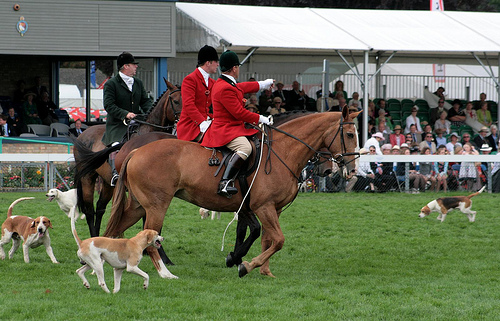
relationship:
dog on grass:
[74, 228, 164, 295] [2, 190, 496, 319]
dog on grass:
[0, 196, 59, 264] [2, 190, 496, 319]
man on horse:
[102, 51, 149, 186] [65, 77, 193, 263]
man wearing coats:
[198, 54, 293, 196] [199, 75, 258, 148]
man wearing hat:
[198, 54, 293, 196] [221, 50, 241, 70]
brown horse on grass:
[98, 103, 363, 277] [337, 196, 455, 291]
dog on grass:
[43, 186, 87, 223] [2, 190, 496, 319]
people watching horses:
[257, 70, 497, 189] [71, 79, 365, 278]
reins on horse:
[262, 111, 361, 183] [103, 106, 360, 276]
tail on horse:
[69, 129, 127, 183] [54, 130, 174, 244]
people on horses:
[97, 40, 277, 209] [71, 79, 365, 278]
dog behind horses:
[43, 186, 87, 223] [71, 79, 365, 278]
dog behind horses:
[74, 228, 164, 295] [71, 79, 365, 278]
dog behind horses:
[0, 193, 57, 266] [71, 79, 365, 278]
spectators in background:
[3, 78, 498, 190] [0, 0, 497, 158]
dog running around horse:
[74, 228, 164, 295] [103, 106, 360, 276]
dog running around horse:
[0, 196, 59, 264] [103, 106, 360, 276]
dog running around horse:
[43, 186, 87, 223] [103, 106, 360, 276]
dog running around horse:
[74, 228, 164, 295] [74, 71, 188, 271]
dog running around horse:
[0, 196, 59, 264] [74, 71, 188, 271]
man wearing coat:
[103, 43, 149, 148] [102, 76, 152, 141]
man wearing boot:
[199, 48, 276, 196] [213, 144, 244, 198]